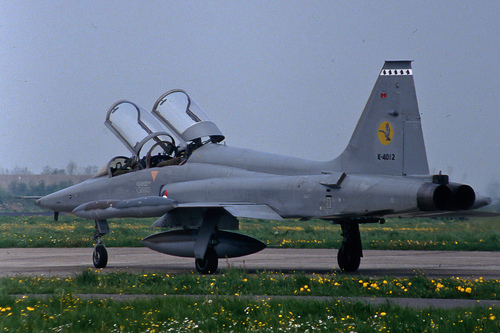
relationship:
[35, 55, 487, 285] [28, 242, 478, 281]
airplane on runway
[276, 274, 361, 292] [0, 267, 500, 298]
flowers in green grass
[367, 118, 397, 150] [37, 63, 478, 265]
design on side of plane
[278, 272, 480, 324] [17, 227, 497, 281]
green grass along runway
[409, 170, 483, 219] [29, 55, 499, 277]
exhaust pipes on back of plane